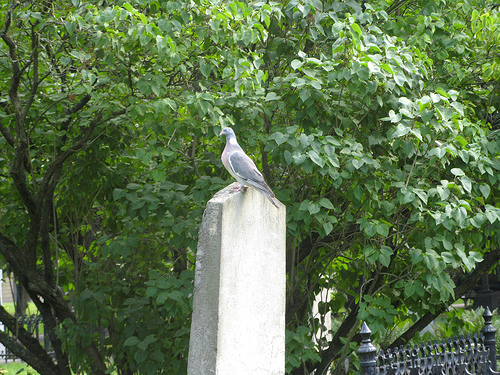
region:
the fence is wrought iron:
[340, 300, 497, 371]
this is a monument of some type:
[179, 174, 297, 374]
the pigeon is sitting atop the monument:
[210, 119, 284, 217]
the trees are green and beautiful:
[1, 10, 498, 368]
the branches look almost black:
[7, 65, 104, 372]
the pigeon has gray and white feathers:
[214, 122, 281, 214]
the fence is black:
[351, 309, 498, 370]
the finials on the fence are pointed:
[353, 301, 499, 353]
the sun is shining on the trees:
[194, 0, 485, 177]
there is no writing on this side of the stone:
[187, 180, 299, 374]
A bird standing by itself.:
[186, 107, 301, 373]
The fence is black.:
[356, 311, 496, 371]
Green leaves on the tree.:
[306, 15, 496, 223]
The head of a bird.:
[208, 115, 239, 142]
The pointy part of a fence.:
[347, 312, 382, 344]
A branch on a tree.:
[33, 100, 120, 197]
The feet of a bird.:
[226, 173, 255, 195]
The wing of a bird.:
[230, 145, 275, 190]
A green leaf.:
[376, 251, 391, 267]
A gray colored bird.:
[201, 114, 291, 222]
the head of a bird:
[215, 120, 237, 140]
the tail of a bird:
[248, 175, 286, 217]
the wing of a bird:
[225, 150, 267, 185]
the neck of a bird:
[221, 134, 243, 146]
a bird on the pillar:
[215, 120, 285, 215]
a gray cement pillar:
[180, 178, 303, 370]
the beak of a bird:
[216, 125, 227, 138]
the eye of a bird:
[223, 125, 232, 133]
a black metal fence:
[350, 300, 497, 374]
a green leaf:
[107, 185, 130, 200]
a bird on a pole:
[147, 60, 340, 372]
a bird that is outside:
[122, 106, 364, 321]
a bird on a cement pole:
[155, 72, 350, 371]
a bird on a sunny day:
[117, 63, 362, 373]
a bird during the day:
[141, 50, 343, 374]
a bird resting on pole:
[149, 85, 363, 369]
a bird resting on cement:
[166, 92, 386, 374]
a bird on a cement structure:
[167, 80, 346, 372]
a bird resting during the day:
[142, 92, 376, 371]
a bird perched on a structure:
[149, 67, 366, 374]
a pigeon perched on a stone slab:
[219, 126, 282, 213]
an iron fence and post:
[359, 306, 497, 373]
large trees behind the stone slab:
[0, 0, 186, 373]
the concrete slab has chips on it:
[187, 206, 286, 374]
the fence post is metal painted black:
[356, 321, 377, 373]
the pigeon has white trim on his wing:
[226, 148, 276, 195]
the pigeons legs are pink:
[229, 183, 247, 195]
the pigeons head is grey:
[217, 126, 234, 136]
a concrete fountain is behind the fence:
[471, 273, 498, 313]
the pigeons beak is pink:
[217, 126, 224, 137]